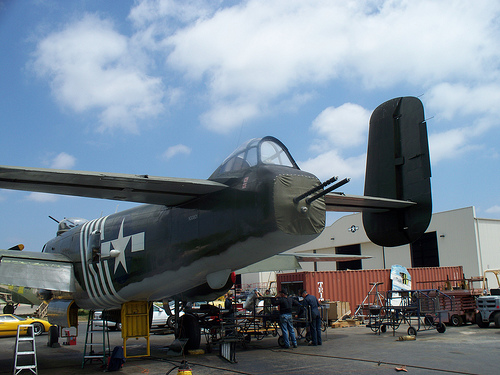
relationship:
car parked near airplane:
[0, 313, 58, 337] [0, 95, 435, 363]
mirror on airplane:
[357, 93, 440, 249] [1, 131, 436, 351]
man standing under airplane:
[270, 288, 307, 349] [0, 95, 435, 363]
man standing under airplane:
[294, 289, 322, 346] [0, 95, 435, 363]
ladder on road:
[11, 322, 42, 373] [0, 320, 498, 373]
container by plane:
[277, 266, 466, 321] [6, 97, 439, 299]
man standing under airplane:
[294, 289, 322, 346] [0, 138, 422, 303]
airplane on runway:
[46, 68, 476, 343] [146, 309, 492, 374]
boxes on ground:
[324, 298, 348, 321] [0, 317, 497, 372]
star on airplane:
[102, 217, 140, 275] [0, 95, 435, 360]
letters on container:
[316, 279, 325, 303] [277, 266, 466, 321]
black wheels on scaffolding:
[435, 321, 446, 333] [374, 327, 489, 352]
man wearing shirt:
[268, 287, 299, 349] [272, 296, 294, 315]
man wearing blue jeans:
[270, 288, 307, 349] [275, 311, 302, 346]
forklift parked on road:
[467, 270, 498, 329] [444, 327, 499, 367]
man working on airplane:
[270, 288, 307, 349] [69, 97, 421, 361]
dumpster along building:
[302, 265, 458, 314] [246, 200, 475, 316]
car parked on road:
[0, 312, 51, 334] [0, 320, 498, 373]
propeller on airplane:
[37, 194, 95, 265] [0, 95, 435, 360]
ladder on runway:
[11, 324, 42, 375] [0, 310, 447, 370]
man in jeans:
[268, 287, 299, 349] [278, 315, 299, 347]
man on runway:
[270, 288, 307, 349] [292, 329, 431, 372]